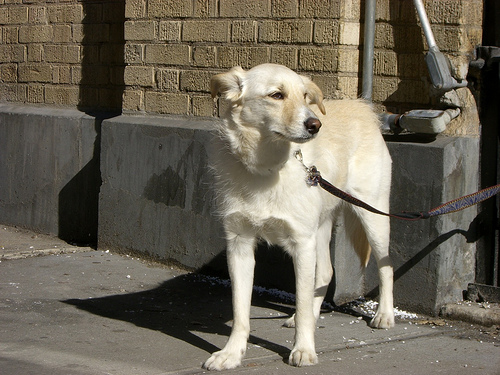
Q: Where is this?
A: This is at the pavement.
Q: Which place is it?
A: It is a pavement.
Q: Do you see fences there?
A: No, there are no fences.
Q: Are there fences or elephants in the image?
A: No, there are no fences or elephants.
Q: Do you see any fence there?
A: No, there are no fences.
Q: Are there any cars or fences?
A: No, there are no fences or cars.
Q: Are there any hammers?
A: No, there are no hammers.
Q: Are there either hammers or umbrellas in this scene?
A: No, there are no hammers or umbrellas.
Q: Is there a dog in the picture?
A: Yes, there is a dog.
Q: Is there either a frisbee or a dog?
A: Yes, there is a dog.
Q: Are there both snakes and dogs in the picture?
A: No, there is a dog but no snakes.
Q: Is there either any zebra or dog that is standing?
A: Yes, the dog is standing.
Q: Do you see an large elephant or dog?
A: Yes, there is a large dog.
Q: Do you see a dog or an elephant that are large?
A: Yes, the dog is large.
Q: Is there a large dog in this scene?
A: Yes, there is a large dog.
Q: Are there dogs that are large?
A: Yes, there is a dog that is large.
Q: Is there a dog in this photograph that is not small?
A: Yes, there is a large dog.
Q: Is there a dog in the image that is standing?
A: Yes, there is a dog that is standing.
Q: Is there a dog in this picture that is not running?
A: Yes, there is a dog that is standing.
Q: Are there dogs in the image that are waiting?
A: Yes, there is a dog that is waiting.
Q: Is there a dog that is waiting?
A: Yes, there is a dog that is waiting.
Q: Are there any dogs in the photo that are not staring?
A: Yes, there is a dog that is waiting.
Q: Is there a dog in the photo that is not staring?
A: Yes, there is a dog that is waiting.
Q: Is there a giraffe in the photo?
A: No, there are no giraffes.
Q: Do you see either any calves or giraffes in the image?
A: No, there are no giraffes or calves.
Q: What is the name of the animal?
A: The animal is a dog.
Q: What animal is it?
A: The animal is a dog.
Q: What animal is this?
A: This is a dog.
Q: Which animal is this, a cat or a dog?
A: This is a dog.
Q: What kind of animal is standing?
A: The animal is a dog.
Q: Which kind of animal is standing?
A: The animal is a dog.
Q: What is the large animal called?
A: The animal is a dog.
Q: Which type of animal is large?
A: The animal is a dog.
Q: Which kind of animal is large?
A: The animal is a dog.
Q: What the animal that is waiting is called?
A: The animal is a dog.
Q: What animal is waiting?
A: The animal is a dog.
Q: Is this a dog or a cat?
A: This is a dog.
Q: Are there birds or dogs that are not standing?
A: No, there is a dog but it is standing.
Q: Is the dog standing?
A: Yes, the dog is standing.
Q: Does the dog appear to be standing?
A: Yes, the dog is standing.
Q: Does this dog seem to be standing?
A: Yes, the dog is standing.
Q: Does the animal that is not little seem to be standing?
A: Yes, the dog is standing.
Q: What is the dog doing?
A: The dog is standing.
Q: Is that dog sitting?
A: No, the dog is standing.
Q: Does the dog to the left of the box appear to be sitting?
A: No, the dog is standing.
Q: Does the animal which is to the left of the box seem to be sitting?
A: No, the dog is standing.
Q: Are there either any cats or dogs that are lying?
A: No, there is a dog but it is standing.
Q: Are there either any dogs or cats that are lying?
A: No, there is a dog but it is standing.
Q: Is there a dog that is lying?
A: No, there is a dog but it is standing.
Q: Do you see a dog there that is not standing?
A: No, there is a dog but it is standing.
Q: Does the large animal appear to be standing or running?
A: The dog is standing.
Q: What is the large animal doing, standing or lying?
A: The dog is standing.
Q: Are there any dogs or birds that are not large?
A: No, there is a dog but it is large.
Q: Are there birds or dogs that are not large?
A: No, there is a dog but it is large.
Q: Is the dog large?
A: Yes, the dog is large.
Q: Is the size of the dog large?
A: Yes, the dog is large.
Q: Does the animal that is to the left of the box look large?
A: Yes, the dog is large.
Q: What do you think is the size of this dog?
A: The dog is large.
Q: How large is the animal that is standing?
A: The dog is large.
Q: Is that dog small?
A: No, the dog is large.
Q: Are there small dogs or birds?
A: No, there is a dog but it is large.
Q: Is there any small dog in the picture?
A: No, there is a dog but it is large.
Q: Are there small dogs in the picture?
A: No, there is a dog but it is large.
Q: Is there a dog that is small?
A: No, there is a dog but it is large.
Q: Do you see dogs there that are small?
A: No, there is a dog but it is large.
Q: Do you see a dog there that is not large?
A: No, there is a dog but it is large.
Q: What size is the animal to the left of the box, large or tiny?
A: The dog is large.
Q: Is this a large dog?
A: Yes, this is a large dog.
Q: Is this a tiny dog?
A: No, this is a large dog.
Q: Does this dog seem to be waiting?
A: Yes, the dog is waiting.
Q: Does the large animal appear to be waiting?
A: Yes, the dog is waiting.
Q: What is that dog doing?
A: The dog is waiting.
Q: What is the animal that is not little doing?
A: The dog is waiting.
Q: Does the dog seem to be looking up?
A: No, the dog is waiting.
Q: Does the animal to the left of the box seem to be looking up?
A: No, the dog is waiting.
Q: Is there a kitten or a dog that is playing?
A: No, there is a dog but it is waiting.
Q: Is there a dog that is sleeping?
A: No, there is a dog but it is waiting.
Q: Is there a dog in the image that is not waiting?
A: No, there is a dog but it is waiting.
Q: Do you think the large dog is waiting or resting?
A: The dog is waiting.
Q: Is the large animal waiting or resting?
A: The dog is waiting.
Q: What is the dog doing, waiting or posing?
A: The dog is waiting.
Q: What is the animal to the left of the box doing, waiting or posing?
A: The dog is waiting.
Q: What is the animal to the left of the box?
A: The animal is a dog.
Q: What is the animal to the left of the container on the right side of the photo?
A: The animal is a dog.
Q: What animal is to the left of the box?
A: The animal is a dog.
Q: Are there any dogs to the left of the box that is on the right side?
A: Yes, there is a dog to the left of the box.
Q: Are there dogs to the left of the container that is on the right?
A: Yes, there is a dog to the left of the box.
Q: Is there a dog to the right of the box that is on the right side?
A: No, the dog is to the left of the box.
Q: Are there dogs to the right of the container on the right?
A: No, the dog is to the left of the box.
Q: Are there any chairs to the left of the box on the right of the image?
A: No, there is a dog to the left of the box.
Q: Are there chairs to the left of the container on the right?
A: No, there is a dog to the left of the box.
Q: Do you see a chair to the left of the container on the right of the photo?
A: No, there is a dog to the left of the box.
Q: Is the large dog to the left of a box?
A: Yes, the dog is to the left of a box.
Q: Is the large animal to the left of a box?
A: Yes, the dog is to the left of a box.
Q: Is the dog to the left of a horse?
A: No, the dog is to the left of a box.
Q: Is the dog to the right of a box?
A: No, the dog is to the left of a box.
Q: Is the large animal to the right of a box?
A: No, the dog is to the left of a box.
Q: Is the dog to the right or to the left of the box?
A: The dog is to the left of the box.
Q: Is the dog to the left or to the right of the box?
A: The dog is to the left of the box.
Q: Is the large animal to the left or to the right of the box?
A: The dog is to the left of the box.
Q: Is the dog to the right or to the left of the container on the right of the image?
A: The dog is to the left of the box.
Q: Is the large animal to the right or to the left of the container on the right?
A: The dog is to the left of the box.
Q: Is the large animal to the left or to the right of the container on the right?
A: The dog is to the left of the box.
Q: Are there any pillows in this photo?
A: No, there are no pillows.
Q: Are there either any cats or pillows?
A: No, there are no pillows or cats.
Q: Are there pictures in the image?
A: No, there are no pictures.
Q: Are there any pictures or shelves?
A: No, there are no pictures or shelves.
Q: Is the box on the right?
A: Yes, the box is on the right of the image.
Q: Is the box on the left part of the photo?
A: No, the box is on the right of the image.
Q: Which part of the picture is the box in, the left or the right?
A: The box is on the right of the image.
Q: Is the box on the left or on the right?
A: The box is on the right of the image.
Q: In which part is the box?
A: The box is on the right of the image.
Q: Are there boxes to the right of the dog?
A: Yes, there is a box to the right of the dog.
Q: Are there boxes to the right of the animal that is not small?
A: Yes, there is a box to the right of the dog.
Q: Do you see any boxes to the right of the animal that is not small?
A: Yes, there is a box to the right of the dog.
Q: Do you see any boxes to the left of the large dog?
A: No, the box is to the right of the dog.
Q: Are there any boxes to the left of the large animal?
A: No, the box is to the right of the dog.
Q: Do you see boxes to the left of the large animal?
A: No, the box is to the right of the dog.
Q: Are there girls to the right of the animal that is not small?
A: No, there is a box to the right of the dog.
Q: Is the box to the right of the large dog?
A: Yes, the box is to the right of the dog.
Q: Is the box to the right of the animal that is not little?
A: Yes, the box is to the right of the dog.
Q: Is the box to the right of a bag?
A: No, the box is to the right of the dog.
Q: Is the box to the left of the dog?
A: No, the box is to the right of the dog.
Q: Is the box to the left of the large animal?
A: No, the box is to the right of the dog.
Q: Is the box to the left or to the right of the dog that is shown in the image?
A: The box is to the right of the dog.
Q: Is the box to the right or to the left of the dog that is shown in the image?
A: The box is to the right of the dog.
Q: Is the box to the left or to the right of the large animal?
A: The box is to the right of the dog.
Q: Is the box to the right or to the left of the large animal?
A: The box is to the right of the dog.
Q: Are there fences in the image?
A: No, there are no fences.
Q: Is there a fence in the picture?
A: No, there are no fences.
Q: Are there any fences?
A: No, there are no fences.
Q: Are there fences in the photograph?
A: No, there are no fences.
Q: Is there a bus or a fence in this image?
A: No, there are no fences or buses.